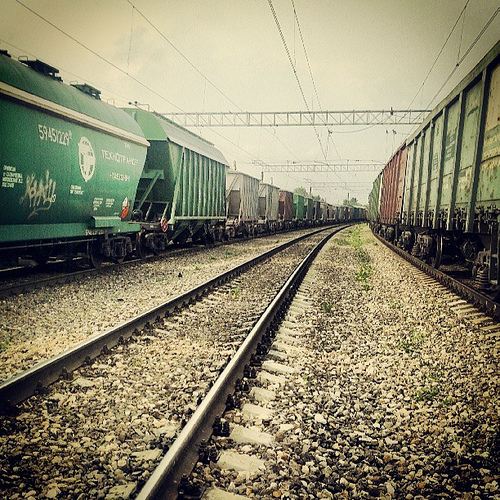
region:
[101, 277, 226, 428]
this is a railway line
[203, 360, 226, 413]
this is the metal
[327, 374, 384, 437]
these are small stones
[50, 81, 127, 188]
this is a train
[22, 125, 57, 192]
the train is green in color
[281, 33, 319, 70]
these are electrical wires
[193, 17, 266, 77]
this is the sky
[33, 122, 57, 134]
this is a writing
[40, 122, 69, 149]
the writing is in white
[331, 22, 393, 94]
the sky is blue in color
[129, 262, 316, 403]
the railway is clear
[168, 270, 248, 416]
the railway is clear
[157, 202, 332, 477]
the railway is clear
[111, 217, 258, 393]
the railway is clear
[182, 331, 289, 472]
the railway is clear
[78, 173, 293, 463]
the railway is clear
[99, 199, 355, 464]
a very long rail way track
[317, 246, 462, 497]
group of stones beside rail way track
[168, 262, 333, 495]
one side of the track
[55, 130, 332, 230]
a good train on track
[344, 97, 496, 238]
a long train on track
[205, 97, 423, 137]
a small bridge on air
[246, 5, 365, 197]
electrical wire on top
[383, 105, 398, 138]
a small connecting in air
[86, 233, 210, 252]
wheels of the train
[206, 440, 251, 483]
a white big stone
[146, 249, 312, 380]
these are two rails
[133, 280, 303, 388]
the rails are metallic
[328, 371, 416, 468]
these are small rocks beside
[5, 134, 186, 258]
these are trains carriages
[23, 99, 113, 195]
the carriage is green in color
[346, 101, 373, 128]
this is a bridge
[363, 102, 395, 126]
the bridge is metallic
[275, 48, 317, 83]
these are the electric wires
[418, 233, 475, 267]
the wheels are metallic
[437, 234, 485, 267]
the wheel aren old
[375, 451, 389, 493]
the stones are black and white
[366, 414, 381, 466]
the stones are black and white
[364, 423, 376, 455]
the stones are black and white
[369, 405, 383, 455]
the stones are black and white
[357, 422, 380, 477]
the stones are black and white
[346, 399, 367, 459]
the stones are black and white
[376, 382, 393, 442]
the stones are black and white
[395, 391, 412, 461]
the stones are black and white